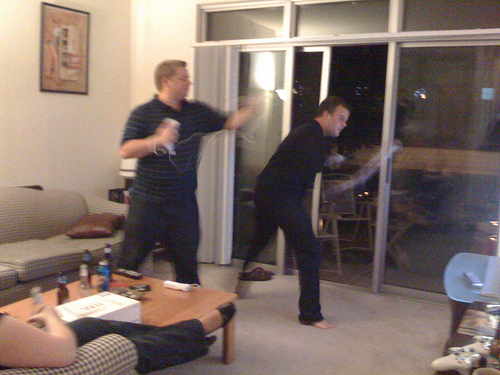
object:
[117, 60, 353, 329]
two men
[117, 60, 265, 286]
man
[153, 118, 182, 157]
wii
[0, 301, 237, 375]
person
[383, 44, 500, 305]
door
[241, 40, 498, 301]
patio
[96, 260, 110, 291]
drinks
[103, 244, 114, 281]
beer bottles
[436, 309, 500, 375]
table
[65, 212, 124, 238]
pillow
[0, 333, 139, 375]
sofa chair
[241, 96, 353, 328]
man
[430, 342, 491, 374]
contoller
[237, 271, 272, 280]
shoes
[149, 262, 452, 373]
floor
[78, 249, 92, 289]
bottles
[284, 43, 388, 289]
door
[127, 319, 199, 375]
leg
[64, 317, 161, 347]
leg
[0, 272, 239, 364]
coffee table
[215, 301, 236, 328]
shoe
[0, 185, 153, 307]
sofa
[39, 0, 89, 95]
frame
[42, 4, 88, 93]
picture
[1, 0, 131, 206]
wall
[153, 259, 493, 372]
ground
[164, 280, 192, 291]
game controller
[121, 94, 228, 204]
shirt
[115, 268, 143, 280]
remote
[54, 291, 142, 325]
box